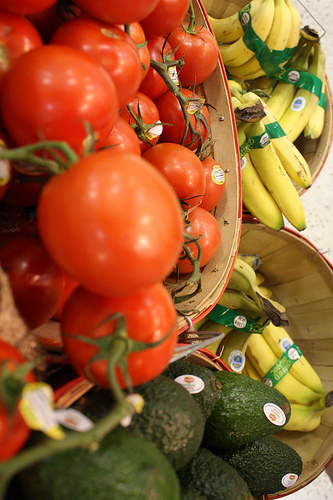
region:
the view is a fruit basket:
[52, 24, 303, 279]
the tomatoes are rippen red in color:
[75, 182, 182, 331]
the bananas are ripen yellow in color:
[270, 340, 324, 406]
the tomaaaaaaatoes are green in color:
[175, 378, 261, 475]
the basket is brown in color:
[282, 241, 329, 326]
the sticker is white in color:
[262, 405, 282, 424]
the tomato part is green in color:
[109, 320, 128, 396]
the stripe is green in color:
[269, 68, 328, 102]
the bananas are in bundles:
[232, 289, 320, 392]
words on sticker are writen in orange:
[263, 399, 291, 425]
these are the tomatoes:
[12, 16, 198, 260]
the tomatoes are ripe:
[17, 35, 193, 250]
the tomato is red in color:
[40, 169, 167, 272]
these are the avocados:
[120, 378, 276, 493]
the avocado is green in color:
[226, 382, 261, 437]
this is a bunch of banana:
[265, 330, 294, 372]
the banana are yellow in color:
[295, 366, 314, 395]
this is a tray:
[288, 247, 317, 288]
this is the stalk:
[162, 67, 181, 92]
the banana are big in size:
[253, 153, 302, 216]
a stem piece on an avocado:
[209, 378, 222, 392]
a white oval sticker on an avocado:
[261, 399, 287, 424]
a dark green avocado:
[224, 433, 303, 496]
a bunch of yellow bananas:
[228, 91, 318, 235]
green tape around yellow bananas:
[235, 118, 284, 164]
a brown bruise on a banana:
[292, 168, 303, 181]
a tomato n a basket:
[164, 16, 225, 92]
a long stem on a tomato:
[0, 334, 134, 498]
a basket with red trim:
[197, 220, 330, 496]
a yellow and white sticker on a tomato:
[207, 162, 228, 187]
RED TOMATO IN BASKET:
[75, 284, 184, 376]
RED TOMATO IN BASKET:
[75, 170, 158, 264]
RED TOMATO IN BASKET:
[181, 221, 229, 279]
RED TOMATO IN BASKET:
[209, 156, 234, 206]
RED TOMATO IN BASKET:
[162, 143, 207, 200]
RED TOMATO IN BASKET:
[25, 54, 96, 132]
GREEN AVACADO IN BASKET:
[75, 429, 169, 498]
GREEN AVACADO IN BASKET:
[125, 372, 209, 448]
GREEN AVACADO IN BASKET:
[206, 456, 249, 493]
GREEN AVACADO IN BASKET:
[218, 375, 285, 422]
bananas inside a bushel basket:
[239, 213, 331, 499]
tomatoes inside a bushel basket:
[0, 1, 241, 388]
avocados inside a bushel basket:
[0, 341, 303, 498]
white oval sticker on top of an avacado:
[263, 403, 282, 422]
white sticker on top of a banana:
[290, 96, 305, 112]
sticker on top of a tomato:
[210, 163, 226, 184]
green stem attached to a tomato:
[1, 140, 79, 175]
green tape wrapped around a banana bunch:
[239, 4, 296, 81]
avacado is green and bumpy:
[206, 369, 290, 449]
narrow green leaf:
[128, 319, 178, 354]